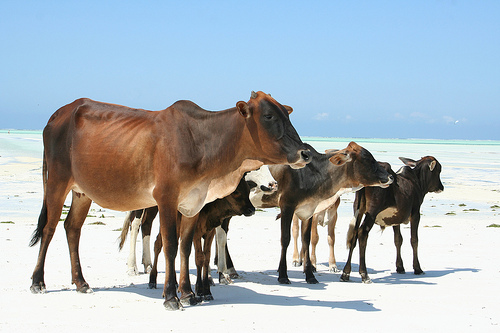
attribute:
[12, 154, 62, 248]
tail — black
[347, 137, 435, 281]
cow — young, black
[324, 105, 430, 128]
clouds — sparse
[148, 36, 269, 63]
skies — blue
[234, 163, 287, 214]
face — partially hidden, white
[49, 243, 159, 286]
beach — white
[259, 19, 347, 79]
sky — blue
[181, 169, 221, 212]
cow chest — white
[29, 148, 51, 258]
tail — long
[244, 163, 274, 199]
head — white